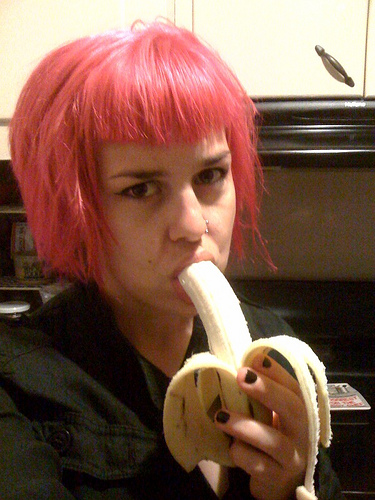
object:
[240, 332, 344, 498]
peelings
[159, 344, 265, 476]
peelings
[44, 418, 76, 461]
button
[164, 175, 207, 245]
nose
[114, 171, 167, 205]
eyes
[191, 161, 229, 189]
eyes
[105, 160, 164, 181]
eyebrow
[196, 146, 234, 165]
eyebrow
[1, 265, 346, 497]
top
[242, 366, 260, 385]
nail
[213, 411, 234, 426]
nail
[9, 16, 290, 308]
hair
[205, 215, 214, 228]
piercing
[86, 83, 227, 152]
bangs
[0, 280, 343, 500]
shirt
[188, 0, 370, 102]
cabinet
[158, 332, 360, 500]
peel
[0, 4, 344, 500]
girl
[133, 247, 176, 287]
birthmark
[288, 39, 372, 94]
handle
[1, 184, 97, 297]
shelves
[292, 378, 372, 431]
object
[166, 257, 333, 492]
fruit